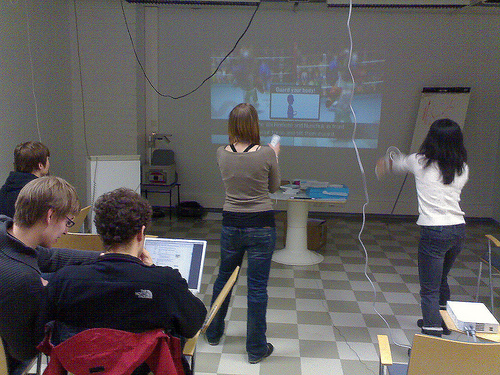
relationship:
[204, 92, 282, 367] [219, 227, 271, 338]
woman wearing jeans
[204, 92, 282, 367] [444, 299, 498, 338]
woman playing wii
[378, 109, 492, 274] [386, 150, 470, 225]
girl in shirt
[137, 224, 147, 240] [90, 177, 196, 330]
ear on man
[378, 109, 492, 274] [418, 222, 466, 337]
girl wearing jeans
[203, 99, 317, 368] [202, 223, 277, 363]
girl wearing jeans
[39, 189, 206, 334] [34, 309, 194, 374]
man has coat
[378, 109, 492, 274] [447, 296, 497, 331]
girl playing a video game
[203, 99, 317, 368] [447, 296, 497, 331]
girl playing a video game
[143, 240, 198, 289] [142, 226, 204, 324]
screen of laptop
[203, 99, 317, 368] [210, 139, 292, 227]
girl has shirt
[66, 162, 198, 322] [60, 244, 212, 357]
man has black jacket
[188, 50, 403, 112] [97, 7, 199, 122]
image on wall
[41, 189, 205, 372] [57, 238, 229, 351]
boy wearing jacket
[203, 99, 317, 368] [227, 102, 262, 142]
girl has hair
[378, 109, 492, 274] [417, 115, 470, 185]
girl has black hair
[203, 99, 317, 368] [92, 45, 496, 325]
girl playing video game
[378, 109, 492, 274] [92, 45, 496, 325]
girl playing video game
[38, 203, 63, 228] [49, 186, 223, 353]
ear on man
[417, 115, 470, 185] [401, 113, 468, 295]
black hair on girl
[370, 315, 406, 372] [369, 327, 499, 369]
arm on desk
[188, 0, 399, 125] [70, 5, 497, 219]
image on wall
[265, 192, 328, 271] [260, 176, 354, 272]
base on table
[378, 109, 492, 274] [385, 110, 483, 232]
girl in shirt